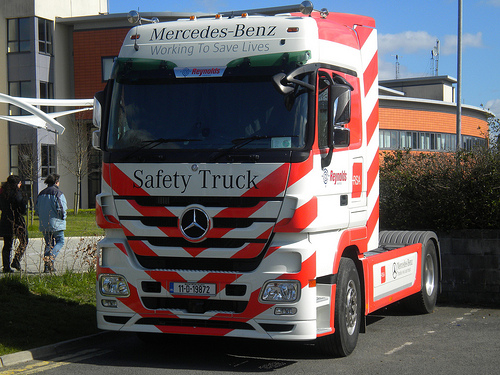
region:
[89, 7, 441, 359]
red and white Mercedes-Benz truck cab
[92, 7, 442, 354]
Mercedes-Benz Safety Truck Cab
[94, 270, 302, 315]
truck cab headlights and turn signal lights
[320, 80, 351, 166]
truck rear view side mirror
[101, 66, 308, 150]
flat front truck cab windshield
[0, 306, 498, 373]
parking lot with faded space markings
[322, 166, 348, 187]
Reynolds company logo on truck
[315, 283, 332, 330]
built in external truck cab stepup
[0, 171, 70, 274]
two young girls walking on sidewalk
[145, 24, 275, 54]
Lettering on truck cab Mercedes-Benz Working To Save Lives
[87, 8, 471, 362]
an orange and white truck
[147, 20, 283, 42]
the words Mercedes-Benz on a truck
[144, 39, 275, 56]
the words Working to Save Lives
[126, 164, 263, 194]
the words Safety Truck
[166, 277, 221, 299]
a license plate on a truck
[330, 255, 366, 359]
tire on a truck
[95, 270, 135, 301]
a headlight on a truck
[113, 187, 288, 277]
the grill of a truck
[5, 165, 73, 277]
people walking on a road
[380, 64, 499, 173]
a building in the distance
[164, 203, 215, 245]
a mercedes logo on a truck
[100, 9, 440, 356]
a large red and white truck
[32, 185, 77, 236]
a blue winter coat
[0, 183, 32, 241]
a black winter coat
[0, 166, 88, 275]
two people walking on a sidewalk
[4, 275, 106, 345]
a patch of grass next to a sidewalk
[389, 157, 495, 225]
a row of bushes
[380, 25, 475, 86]
a patch of clouds in the sky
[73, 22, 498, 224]
a large brick building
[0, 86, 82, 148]
a white overhang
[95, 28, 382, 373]
red and white truck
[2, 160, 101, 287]
people walking at the sidewalk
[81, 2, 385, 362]
the front of a truck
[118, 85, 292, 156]
the windshield of a truck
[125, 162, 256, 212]
the logo of a truck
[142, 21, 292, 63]
the title of a truck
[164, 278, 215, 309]
the license plate of a truck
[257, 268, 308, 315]
the head light of a truck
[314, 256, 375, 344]
the front wheel of a truck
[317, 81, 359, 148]
the side window of a truck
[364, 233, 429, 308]
the side of a truck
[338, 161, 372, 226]
the door of a truck